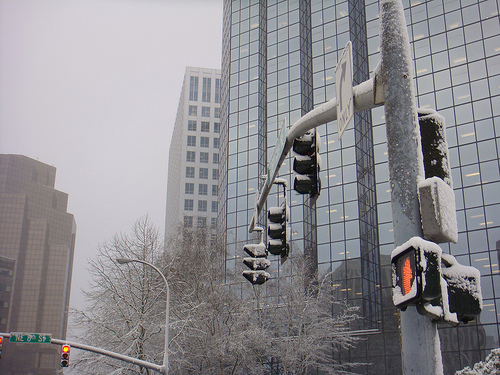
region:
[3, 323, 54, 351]
Street sign topped with snow.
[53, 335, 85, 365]
Red light stops traffic.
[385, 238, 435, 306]
Pedestrian don't walk.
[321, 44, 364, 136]
Sign is no left turn.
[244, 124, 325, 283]
Three sets traffic lights.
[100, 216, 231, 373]
Trees glazed with snow.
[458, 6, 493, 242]
Office lights are on.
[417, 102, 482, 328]
Miscellaneous electrical equipment.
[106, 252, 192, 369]
Street light encased in snow.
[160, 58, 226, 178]
Taller windows at the top.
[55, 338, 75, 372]
the stoplight is red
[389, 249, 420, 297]
a hand means don't go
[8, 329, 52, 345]
the street sign is green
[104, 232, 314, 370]
the trees have no leaves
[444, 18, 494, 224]
lights are visible in building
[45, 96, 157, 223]
the sky is grey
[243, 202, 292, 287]
snow covered stoplights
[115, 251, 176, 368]
a white light pole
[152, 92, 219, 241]
a white building with windows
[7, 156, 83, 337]
building with interesting architecture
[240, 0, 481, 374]
the pole has snow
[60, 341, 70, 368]
the light is red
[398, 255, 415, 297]
the hand is lit up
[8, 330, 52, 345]
the sign is green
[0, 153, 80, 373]
the building is tall and brown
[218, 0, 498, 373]
the building is made of glass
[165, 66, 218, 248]
the building has many windows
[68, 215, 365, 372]
the tree has snow on the branches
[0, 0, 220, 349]
the sky is white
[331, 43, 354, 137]
the sign is right turn only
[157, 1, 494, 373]
the buildings have many windows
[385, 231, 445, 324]
the pedestrian light has an orange hand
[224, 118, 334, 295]
the traffic light is covered in snow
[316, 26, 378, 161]
the sign is black and white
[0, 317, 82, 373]
traffic light is glowing red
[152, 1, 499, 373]
the buildings are tall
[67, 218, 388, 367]
the tree branches are covered in snow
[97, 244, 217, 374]
the street light pole is silver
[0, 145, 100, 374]
one of the buildings is brown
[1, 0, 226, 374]
the sky is gray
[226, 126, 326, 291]
three stoplights in a row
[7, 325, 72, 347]
NE 8th street sign on pole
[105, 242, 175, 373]
streetlight on metal pole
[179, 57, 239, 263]
skycraper with many windows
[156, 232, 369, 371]
snow covered trees in winter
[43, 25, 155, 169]
very cloudy winter sky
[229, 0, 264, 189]
glass office windows on side of building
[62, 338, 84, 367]
red light on pole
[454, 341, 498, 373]
small snow covered tree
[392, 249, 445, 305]
red no walking sign is lit